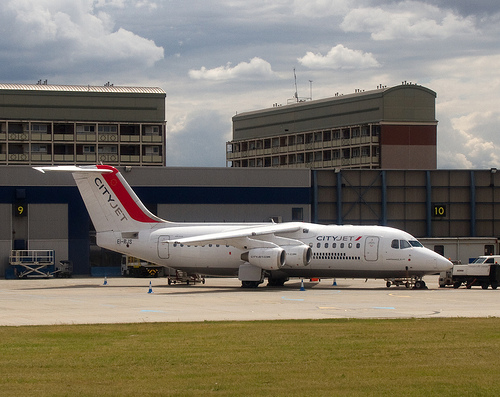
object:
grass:
[107, 320, 419, 393]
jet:
[32, 162, 453, 287]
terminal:
[5, 232, 499, 334]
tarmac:
[2, 271, 495, 326]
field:
[2, 317, 500, 390]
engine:
[239, 243, 286, 268]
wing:
[160, 222, 298, 246]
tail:
[30, 161, 155, 223]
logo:
[90, 172, 132, 227]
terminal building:
[4, 167, 499, 249]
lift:
[5, 247, 59, 278]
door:
[365, 235, 378, 261]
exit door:
[156, 233, 171, 257]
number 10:
[434, 205, 444, 215]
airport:
[5, 237, 492, 394]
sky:
[2, 4, 491, 83]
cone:
[145, 281, 156, 293]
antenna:
[291, 66, 300, 101]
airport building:
[225, 82, 440, 168]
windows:
[8, 141, 32, 154]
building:
[1, 84, 168, 164]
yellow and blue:
[308, 302, 396, 311]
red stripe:
[90, 157, 167, 229]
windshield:
[391, 240, 400, 250]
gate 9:
[16, 204, 25, 215]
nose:
[421, 245, 456, 271]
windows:
[357, 241, 362, 246]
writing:
[315, 235, 325, 241]